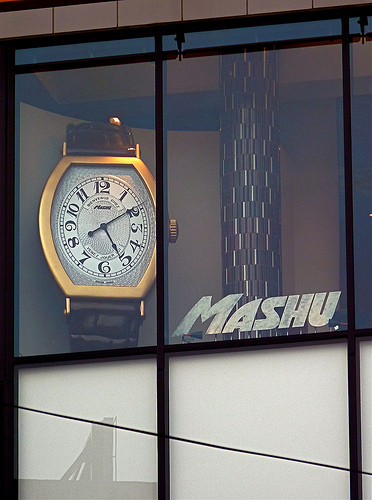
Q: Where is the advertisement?
A: On a building.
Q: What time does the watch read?
A: 5:10.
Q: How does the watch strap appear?
A: Brown and leather.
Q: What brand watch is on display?
A: Mashu.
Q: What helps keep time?
A: Watch.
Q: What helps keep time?
A: Watch.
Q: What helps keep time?
A: Watch.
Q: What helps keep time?
A: Watch.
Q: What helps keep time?
A: Watch.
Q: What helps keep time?
A: Watch.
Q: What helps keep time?
A: Watch.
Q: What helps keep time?
A: Watch.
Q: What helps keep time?
A: Watch.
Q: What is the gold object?
A: Clock frame.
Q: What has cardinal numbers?
A: Clock.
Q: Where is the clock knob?
A: Right side.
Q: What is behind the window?
A: Pole.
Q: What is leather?
A: Clock strap.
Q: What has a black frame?
A: Window.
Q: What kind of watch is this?
A: Wrist.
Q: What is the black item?
A: Pillar.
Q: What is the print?
A: Writing.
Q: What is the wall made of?
A: Glass.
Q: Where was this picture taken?
A: In front of a store.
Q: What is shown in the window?
A: A watch.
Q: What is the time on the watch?
A: 5:10.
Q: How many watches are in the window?
A: One.